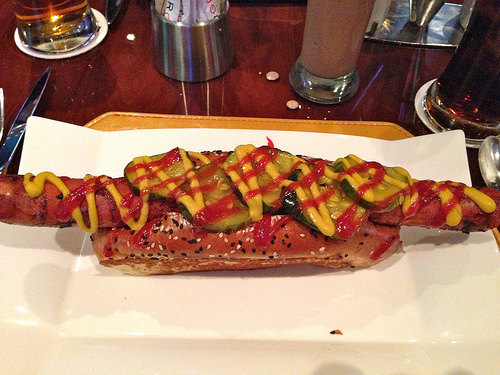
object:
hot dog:
[0, 174, 500, 235]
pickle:
[122, 153, 189, 201]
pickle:
[177, 161, 253, 231]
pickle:
[225, 147, 296, 215]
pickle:
[286, 158, 366, 240]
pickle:
[335, 154, 410, 209]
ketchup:
[100, 154, 150, 228]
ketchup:
[193, 194, 242, 228]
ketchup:
[229, 145, 278, 187]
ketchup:
[283, 157, 336, 236]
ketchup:
[337, 161, 387, 196]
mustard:
[465, 189, 495, 212]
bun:
[93, 212, 399, 274]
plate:
[1, 117, 500, 373]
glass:
[288, 0, 376, 106]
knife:
[1, 69, 50, 175]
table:
[0, 0, 499, 375]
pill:
[266, 71, 279, 80]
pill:
[285, 100, 299, 109]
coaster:
[14, 8, 109, 60]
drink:
[12, 0, 96, 55]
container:
[150, 0, 230, 84]